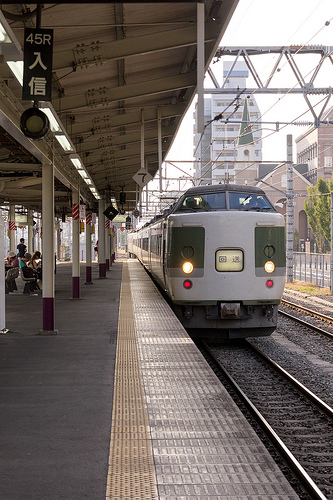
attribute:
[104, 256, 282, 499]
platform bricks — long 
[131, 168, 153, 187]
sign — white 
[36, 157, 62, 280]
post — metal , Large 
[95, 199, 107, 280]
metal post — Large , metal 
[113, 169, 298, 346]
train — long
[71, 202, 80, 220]
patch — white, red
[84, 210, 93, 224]
patch — white, red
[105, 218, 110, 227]
patch — white, red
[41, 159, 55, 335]
post — metal , Large 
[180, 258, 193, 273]
light — yellow , bright 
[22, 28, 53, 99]
sign — black 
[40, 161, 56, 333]
column — purpler , white 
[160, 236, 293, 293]
light — bright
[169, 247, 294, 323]
light — bright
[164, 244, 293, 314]
light — bright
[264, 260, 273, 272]
light — bright